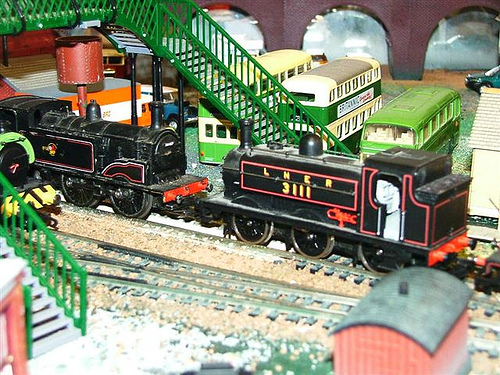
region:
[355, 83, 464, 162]
Green train car model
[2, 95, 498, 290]
Black model train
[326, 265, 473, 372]
Model red barn with a black roof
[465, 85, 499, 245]
White model building with white roof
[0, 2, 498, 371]
Model train cars and train station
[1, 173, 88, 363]
Green staircase railing with gray stairs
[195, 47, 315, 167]
Green and yellow model train car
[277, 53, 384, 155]
Two story model train car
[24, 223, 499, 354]
Model train tracks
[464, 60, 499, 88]
Dark teal car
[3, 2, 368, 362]
Green railing following the stairs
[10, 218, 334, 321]
Track splits into two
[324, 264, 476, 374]
Little red house with black roof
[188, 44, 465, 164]
Three buses in a row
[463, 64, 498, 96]
The front end of a green car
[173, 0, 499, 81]
A structure with three arches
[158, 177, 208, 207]
Red paint on the front of the train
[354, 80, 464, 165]
Small bright green bus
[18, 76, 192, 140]
Truck backed up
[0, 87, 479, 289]
Two engines facing eachother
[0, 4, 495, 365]
a model train station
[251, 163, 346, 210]
lettering that says LNER 3111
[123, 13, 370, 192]
a stairway leading to a bridge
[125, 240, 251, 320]
train tracks crossing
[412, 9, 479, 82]
a model archway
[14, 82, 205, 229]
a black model train engine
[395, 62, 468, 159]
a model vw van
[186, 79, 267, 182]
a model double decker bus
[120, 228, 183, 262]
gravel between the tracks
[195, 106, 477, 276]
toy train steam engine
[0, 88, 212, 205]
toy train steam engine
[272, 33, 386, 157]
green double decker bus toy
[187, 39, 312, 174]
green double decker bus toy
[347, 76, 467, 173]
green toy bus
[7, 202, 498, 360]
toy rail road track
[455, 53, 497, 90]
front of a green toy car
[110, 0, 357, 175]
long green stair railing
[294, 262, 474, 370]
small red building with a curved black roof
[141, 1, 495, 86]
red brick arch ways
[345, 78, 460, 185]
THE BUS IS GREEN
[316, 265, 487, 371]
THE BARN IS RED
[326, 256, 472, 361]
THE ROOF IS BLACK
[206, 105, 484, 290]
THE TRAIN IS BLACK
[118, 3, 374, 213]
THE STAIRS ARE GREEN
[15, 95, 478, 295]
THE TRAIN IS PLASTIC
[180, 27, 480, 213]
THE BUSES ARE PLASTIC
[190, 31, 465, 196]
THE BUSES ARE IN A ROW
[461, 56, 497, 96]
THE LITTLE CAR IS GREEN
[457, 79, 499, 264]
THE BUILDING IS WHITE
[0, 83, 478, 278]
long large metal train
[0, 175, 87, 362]
long short green stairs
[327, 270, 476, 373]
small short red house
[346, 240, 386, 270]
wheel on a train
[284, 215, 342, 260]
wheel on a train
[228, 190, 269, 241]
wheel on a train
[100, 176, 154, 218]
wheel on a train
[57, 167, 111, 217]
wheel on a train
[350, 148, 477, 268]
train on a track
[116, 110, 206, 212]
train on a track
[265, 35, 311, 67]
train in a train set